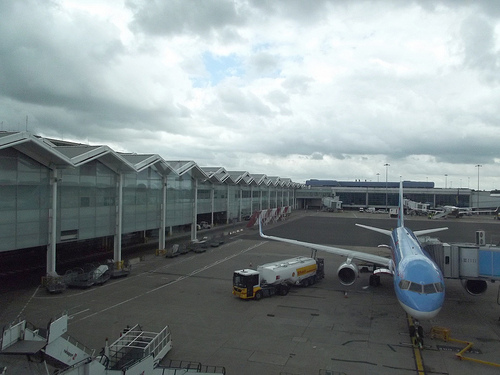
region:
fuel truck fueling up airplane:
[236, 245, 327, 298]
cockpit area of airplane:
[394, 263, 449, 305]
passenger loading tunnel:
[423, 236, 498, 278]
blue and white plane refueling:
[258, 217, 472, 339]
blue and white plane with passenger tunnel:
[283, 215, 497, 307]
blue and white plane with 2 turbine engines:
[324, 214, 498, 321]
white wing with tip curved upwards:
[254, 214, 407, 264]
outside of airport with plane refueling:
[18, 134, 495, 367]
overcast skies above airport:
[238, 80, 470, 240]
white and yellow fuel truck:
[231, 252, 326, 301]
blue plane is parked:
[257, 180, 497, 322]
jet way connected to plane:
[414, 235, 499, 280]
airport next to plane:
[0, 131, 472, 283]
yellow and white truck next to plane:
[233, 255, 325, 302]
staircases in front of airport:
[0, 312, 228, 373]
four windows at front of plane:
[398, 277, 443, 294]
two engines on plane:
[338, 257, 488, 296]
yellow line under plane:
[405, 312, 426, 373]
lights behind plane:
[376, 162, 483, 190]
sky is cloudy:
[0, 0, 499, 192]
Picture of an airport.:
[17, 76, 484, 373]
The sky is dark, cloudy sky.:
[63, 105, 284, 154]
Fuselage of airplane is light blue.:
[388, 222, 447, 316]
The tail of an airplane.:
[359, 183, 445, 236]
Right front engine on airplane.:
[331, 247, 364, 294]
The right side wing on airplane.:
[253, 214, 393, 264]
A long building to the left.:
[14, 125, 303, 254]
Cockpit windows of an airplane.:
[396, 271, 450, 300]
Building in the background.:
[309, 167, 434, 214]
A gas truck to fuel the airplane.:
[218, 245, 338, 304]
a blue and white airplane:
[257, 176, 499, 321]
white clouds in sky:
[350, 90, 421, 119]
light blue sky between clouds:
[209, 61, 227, 73]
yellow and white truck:
[230, 253, 323, 301]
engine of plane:
[338, 255, 358, 285]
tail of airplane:
[354, 177, 450, 239]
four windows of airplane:
[399, 276, 445, 295]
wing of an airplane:
[257, 214, 394, 273]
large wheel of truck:
[253, 290, 261, 298]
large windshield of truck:
[232, 273, 249, 286]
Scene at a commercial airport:
[33, 73, 488, 352]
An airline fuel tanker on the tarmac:
[229, 249, 325, 305]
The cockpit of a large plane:
[396, 265, 448, 317]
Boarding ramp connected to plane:
[411, 228, 498, 285]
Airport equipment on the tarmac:
[323, 191, 480, 223]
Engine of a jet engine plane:
[327, 245, 362, 290]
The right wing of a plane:
[251, 215, 396, 267]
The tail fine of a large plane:
[394, 169, 408, 235]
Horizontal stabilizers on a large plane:
[351, 218, 454, 239]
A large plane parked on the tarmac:
[246, 183, 498, 328]